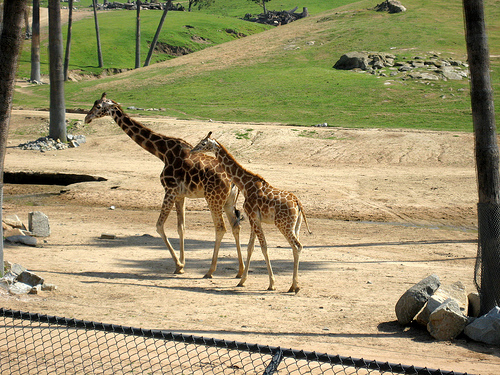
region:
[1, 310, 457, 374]
A fence near the giraffes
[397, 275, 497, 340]
Large rocks by the tree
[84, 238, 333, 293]
A shadow on the ground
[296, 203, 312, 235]
The tail of the giraffe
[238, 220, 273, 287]
The front legs of the giraffe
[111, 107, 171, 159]
The giraffe has a long neck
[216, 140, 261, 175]
The mane of the giraffe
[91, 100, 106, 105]
The left eye of the giraffe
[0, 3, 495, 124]
Grass near the giraffes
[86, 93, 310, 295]
Two giraffes standing near the tree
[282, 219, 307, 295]
leg of a giraffe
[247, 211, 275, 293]
leg of a giraffe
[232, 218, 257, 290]
leg of a giraffe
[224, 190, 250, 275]
leg of a giraffe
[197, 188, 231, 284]
leg of a giraffe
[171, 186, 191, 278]
leg of a giraffe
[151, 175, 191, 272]
leg of a giraffe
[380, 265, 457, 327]
large rock in the zoo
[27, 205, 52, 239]
large rock in the zoo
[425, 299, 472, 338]
large rock in the zoo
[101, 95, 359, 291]
two giraffes walking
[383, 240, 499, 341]
large rocks for landscaping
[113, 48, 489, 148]
beyond the dirt lies green grass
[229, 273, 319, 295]
the hooves of the giraffe are cloven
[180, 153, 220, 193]
brown spots decorate the hide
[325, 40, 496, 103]
rocks jut out from the earth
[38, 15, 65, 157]
a tree trunk to the left shows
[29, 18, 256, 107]
a ravine in the background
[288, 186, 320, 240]
the smaller giraffe tail is not fuzzy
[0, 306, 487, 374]
Grey fence near the giraffe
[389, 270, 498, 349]
Cluster of rocks on the ground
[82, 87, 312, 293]
Two giraffes on the field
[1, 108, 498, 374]
Sandy area on the field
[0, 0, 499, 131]
Grassy area on the slope field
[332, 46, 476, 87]
Cluster of rocks on the slope field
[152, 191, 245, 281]
Giraffe's legs walking on the field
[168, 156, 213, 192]
Brown spots on the giraffe's body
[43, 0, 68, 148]
Brown trunk in the field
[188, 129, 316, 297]
Baby giraffe next to another giraffe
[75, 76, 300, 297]
giraffes walking side by side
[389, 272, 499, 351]
rocks on the ground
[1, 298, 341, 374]
metal fence around area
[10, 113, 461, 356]
dirt surface where giraffes walk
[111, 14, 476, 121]
green space behind giraffes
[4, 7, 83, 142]
trunks of the trees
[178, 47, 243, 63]
patch of bare land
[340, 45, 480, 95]
group of rocks on grass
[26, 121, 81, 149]
rocks around base of tree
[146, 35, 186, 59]
dirt patch in grass